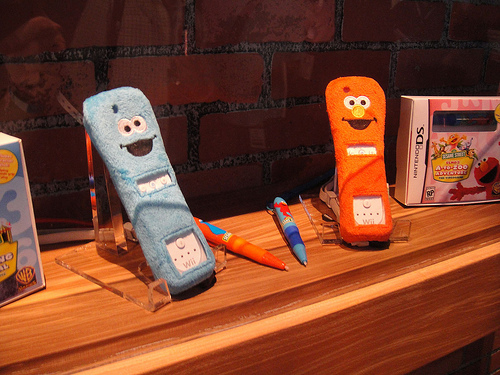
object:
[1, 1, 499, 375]
display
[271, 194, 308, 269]
stylus pen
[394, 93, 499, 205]
ds game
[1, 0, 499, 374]
sesame street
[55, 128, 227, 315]
plastic stand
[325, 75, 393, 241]
wii game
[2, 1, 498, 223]
brick wall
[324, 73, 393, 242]
orange cover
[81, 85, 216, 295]
blue cover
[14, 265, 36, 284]
warner brothers logo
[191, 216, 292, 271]
orange pen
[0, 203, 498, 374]
wooden shelf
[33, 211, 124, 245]
plug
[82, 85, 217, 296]
wii remotes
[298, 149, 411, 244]
remote holder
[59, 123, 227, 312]
stand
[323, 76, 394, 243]
wii controller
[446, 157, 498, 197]
elmo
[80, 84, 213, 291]
wii controller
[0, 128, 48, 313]
game box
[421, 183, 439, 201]
rp logo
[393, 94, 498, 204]
box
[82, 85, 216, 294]
cover